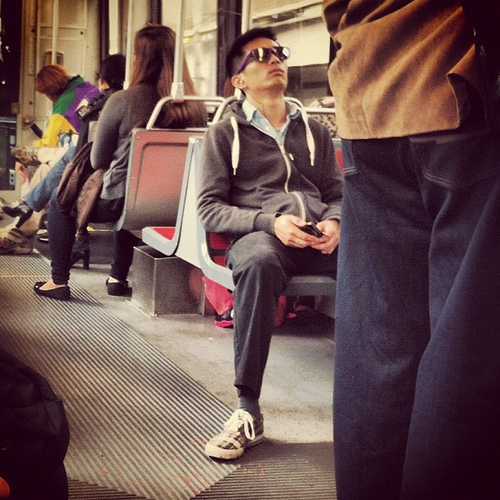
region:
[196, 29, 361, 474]
the man is wearing sunglasses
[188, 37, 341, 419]
the man is sitting on a chair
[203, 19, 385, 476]
the man is sleeping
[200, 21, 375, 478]
the man has a grey hoodie on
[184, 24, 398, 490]
the man has grey pants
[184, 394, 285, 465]
he is wearing plaid shoes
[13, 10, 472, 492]
many people are on the train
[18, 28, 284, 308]
the seats are metal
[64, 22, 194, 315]
the woman is sitting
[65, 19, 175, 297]
she has a brown jacket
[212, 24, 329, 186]
Man is sleeping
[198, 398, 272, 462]
Plaid sneakers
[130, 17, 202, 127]
Woman has long hair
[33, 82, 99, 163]
Person wearing a purple, yellow, green, and white jacket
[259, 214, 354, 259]
Person holding a cell phone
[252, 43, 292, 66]
Person wearing sunglasses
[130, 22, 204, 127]
Lady has auburn hair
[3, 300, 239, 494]
Non-skid walkway on train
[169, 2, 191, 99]
Metal pole to hold onto when standing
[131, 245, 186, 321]
Metal box underneath seat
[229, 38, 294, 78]
this is a pair of sunglasses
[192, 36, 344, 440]
this is a man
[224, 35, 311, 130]
the man is sleeping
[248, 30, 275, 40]
the hair is black in color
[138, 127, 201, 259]
these are seats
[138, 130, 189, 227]
the seats are metallic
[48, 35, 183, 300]
this is a woman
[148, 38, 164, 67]
the hair is brown in color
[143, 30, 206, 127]
the hair is long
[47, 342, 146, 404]
this is a floor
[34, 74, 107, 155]
white, yellow, purple and green coat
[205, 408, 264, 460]
plaid sneakers on man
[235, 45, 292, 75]
black sunglasses on man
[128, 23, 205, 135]
woman's straight, long, auburn hair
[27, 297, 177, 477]
striped, grated carpet on subway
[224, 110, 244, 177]
shoestring on man's hoodie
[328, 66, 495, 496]
man's dark blue jeans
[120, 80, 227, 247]
silver metal subway chair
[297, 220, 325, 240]
small cell phone in man's hand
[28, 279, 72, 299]
black ballet slipper on woman's foot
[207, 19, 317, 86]
Man is wearing sunglasses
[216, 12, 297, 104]
Sunglasses are wearing a purple rim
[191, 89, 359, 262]
Man is wearing a gray hoodie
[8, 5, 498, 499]
People are on a subway train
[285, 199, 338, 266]
Man is holding a cell phone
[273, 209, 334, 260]
Cell phone is black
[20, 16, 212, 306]
A woman is in the background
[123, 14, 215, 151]
Woman has long brown hair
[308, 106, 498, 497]
Person wearing blue jeans is in the foreground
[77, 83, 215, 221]
Woman in the background is wearing a gray shirt